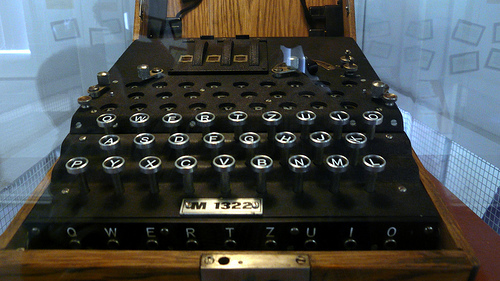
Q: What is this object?
A: A teletype.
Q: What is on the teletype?
A: Keys for letters.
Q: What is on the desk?
A: A typewriter.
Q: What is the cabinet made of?
A: Wood.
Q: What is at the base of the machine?
A: Letters.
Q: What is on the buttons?
A: Alphabet.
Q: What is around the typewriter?
A: White curtain with black boxes.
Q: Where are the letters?
A: On the keys.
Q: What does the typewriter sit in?
A: Wooden box.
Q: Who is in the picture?
A: No one.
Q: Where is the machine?
A: Behind the glass.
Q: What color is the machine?
A: Black.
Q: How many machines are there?
A: One.